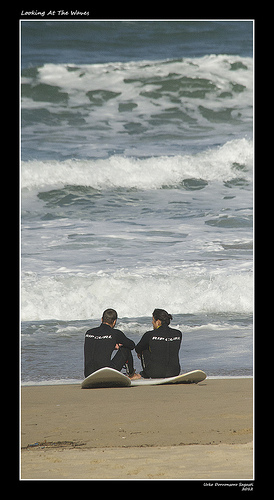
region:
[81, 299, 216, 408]
two people sitting by ocean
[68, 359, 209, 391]
two white surfboards on sand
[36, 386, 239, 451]
smooth tan sand on beach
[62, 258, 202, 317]
white seafoam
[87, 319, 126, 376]
black wetsuit with white text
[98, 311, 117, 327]
man with short hair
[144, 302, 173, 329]
woman with short hair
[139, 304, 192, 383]
woman wearing black wetsuit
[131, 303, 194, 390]
woman sitting on a surfboard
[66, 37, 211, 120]
small ocean wave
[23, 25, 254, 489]
a scene outside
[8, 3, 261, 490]
a scene happening during the day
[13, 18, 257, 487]
a scene of two people next to the ocean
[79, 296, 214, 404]
two people sitting on the shoreline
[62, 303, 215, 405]
two people on their surfboards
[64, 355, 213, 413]
a couple of white surfboards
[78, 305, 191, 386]
two people in black attire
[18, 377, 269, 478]
some wet sand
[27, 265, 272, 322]
a white wave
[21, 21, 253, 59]
some blue water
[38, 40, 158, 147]
a body of water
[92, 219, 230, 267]
a body of blue water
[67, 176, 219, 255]
a body of water that is blue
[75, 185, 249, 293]
a body of wavy water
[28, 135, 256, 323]
a body of water that is wavy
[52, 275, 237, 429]
two people sitting on surfboards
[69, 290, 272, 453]
two people sitting on the beach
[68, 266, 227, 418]
two people sitting on the sand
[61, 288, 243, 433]
two people wearing wetsuits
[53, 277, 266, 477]
two people looking at the water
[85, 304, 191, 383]
two people at th beach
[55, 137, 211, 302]
the water is raging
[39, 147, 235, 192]
the wave in the ocean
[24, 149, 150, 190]
the wave is rolling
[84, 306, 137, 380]
the person is sitting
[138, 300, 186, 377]
the person is sitting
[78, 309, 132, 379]
the person on a surfboard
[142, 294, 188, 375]
the person on a surfboard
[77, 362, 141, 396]
the surfboard is white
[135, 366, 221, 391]
the surfboard is white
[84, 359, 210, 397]
the boards are white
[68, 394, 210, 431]
the sand is brown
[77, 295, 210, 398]
the people are sitting on the boards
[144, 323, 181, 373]
the woman is wearing a body suit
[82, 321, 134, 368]
the man is wearing a body suit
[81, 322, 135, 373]
the body suit is black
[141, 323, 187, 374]
the body suit is black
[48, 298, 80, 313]
the water is white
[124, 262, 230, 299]
the wave is crashing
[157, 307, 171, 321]
the woman has hair